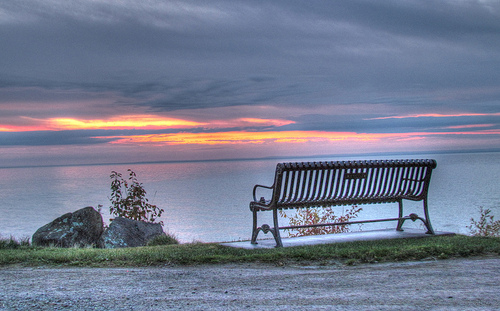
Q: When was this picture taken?
A: Evening.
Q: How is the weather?
A: Cloudy.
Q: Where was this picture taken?
A: The park.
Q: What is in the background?
A: Water.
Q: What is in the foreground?
A: Sand.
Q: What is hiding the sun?
A: Clouds.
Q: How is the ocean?
A: Calm.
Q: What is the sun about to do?
A: Set.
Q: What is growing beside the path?
A: Short green grass.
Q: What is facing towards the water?
A: A metal bench.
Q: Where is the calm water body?
A: Next to a park.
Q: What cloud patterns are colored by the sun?
A: Orange and pink.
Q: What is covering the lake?
A: An overcast sky.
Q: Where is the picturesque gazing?
A: Over the water.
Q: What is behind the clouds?
A: Orange sunset.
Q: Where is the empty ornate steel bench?
A: In a park.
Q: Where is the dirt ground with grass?
A: On edge of dirt.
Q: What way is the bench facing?
A: Toward the water.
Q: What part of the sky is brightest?
A: The part at the horizon.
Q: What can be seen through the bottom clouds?
A: Sunlight.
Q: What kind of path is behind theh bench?
A: A dirt path.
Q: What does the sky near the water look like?
A: Cloudy with peeks of the setting sun.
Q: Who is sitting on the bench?
A: No one.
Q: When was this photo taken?
A: Sunset.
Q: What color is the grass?
A: Green.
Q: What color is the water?
A: Blue.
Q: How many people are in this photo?
A: Zero.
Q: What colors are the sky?
A: Blue and orange.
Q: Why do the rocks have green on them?
A: Moss.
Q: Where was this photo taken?
A: Lake.